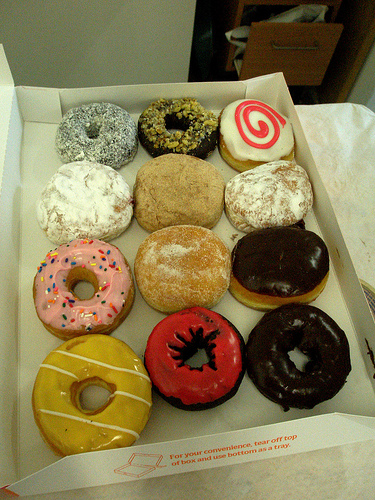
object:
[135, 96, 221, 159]
donuts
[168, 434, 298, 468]
instructions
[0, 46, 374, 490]
box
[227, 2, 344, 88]
drawer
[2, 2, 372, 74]
back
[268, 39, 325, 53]
handle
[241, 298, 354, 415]
donut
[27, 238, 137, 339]
donut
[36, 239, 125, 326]
sprinkles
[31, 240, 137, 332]
frosting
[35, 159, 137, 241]
donut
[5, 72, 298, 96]
edge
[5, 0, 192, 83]
surface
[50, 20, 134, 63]
part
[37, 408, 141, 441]
lines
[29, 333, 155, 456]
donut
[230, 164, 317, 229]
powder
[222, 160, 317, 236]
donut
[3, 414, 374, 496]
side of cardboard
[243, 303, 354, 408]
frosting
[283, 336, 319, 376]
hole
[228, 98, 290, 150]
swirl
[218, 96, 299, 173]
donut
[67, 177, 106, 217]
no hole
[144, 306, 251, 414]
donut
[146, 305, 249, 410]
frosting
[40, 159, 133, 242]
powdered sugar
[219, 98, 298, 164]
frosting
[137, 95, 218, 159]
donut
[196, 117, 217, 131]
nuts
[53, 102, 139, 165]
doughnut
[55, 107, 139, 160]
powdered sugar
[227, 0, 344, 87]
bag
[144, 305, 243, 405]
cream